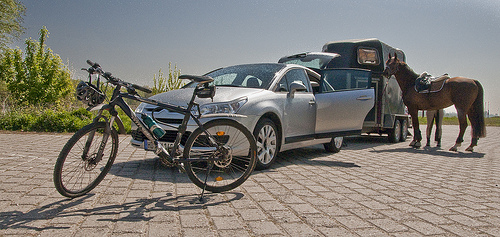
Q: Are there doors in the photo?
A: Yes, there is a door.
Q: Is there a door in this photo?
A: Yes, there is a door.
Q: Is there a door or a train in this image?
A: Yes, there is a door.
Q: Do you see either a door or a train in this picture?
A: Yes, there is a door.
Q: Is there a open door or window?
A: Yes, there is an open door.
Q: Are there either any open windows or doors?
A: Yes, there is an open door.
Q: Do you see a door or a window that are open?
A: Yes, the door is open.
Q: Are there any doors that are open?
A: Yes, there is an open door.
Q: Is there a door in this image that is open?
A: Yes, there is a door that is open.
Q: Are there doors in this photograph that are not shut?
A: Yes, there is a open door.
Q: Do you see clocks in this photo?
A: No, there are no clocks.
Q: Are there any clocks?
A: No, there are no clocks.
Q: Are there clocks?
A: No, there are no clocks.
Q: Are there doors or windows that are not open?
A: No, there is a door but it is open.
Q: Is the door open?
A: Yes, the door is open.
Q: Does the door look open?
A: Yes, the door is open.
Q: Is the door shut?
A: No, the door is open.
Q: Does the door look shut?
A: No, the door is open.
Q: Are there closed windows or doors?
A: No, there is a door but it is open.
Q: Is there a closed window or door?
A: No, there is a door but it is open.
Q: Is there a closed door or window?
A: No, there is a door but it is open.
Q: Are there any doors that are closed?
A: No, there is a door but it is open.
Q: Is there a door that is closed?
A: No, there is a door but it is open.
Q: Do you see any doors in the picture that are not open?
A: No, there is a door but it is open.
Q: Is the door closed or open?
A: The door is open.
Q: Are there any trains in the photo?
A: No, there are no trains.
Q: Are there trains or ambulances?
A: No, there are no trains or ambulances.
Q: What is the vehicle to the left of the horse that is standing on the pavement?
A: The vehicle is a trailer.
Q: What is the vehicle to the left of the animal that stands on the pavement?
A: The vehicle is a trailer.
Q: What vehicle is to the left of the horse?
A: The vehicle is a trailer.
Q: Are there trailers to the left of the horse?
A: Yes, there is a trailer to the left of the horse.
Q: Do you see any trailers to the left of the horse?
A: Yes, there is a trailer to the left of the horse.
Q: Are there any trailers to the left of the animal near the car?
A: Yes, there is a trailer to the left of the horse.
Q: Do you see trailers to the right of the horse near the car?
A: No, the trailer is to the left of the horse.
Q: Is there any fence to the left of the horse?
A: No, there is a trailer to the left of the horse.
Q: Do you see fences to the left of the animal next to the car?
A: No, there is a trailer to the left of the horse.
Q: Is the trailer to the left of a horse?
A: Yes, the trailer is to the left of a horse.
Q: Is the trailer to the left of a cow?
A: No, the trailer is to the left of a horse.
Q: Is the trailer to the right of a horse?
A: No, the trailer is to the left of a horse.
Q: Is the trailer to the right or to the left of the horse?
A: The trailer is to the left of the horse.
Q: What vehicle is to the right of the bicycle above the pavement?
A: The vehicle is a trailer.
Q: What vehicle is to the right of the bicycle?
A: The vehicle is a trailer.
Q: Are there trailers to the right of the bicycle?
A: Yes, there is a trailer to the right of the bicycle.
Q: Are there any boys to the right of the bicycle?
A: No, there is a trailer to the right of the bicycle.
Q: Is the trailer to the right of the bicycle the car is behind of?
A: Yes, the trailer is to the right of the bicycle.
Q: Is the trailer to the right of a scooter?
A: No, the trailer is to the right of the bicycle.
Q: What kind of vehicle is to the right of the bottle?
A: The vehicle is a trailer.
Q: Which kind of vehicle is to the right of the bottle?
A: The vehicle is a trailer.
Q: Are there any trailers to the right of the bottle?
A: Yes, there is a trailer to the right of the bottle.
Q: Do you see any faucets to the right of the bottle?
A: No, there is a trailer to the right of the bottle.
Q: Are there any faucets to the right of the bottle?
A: No, there is a trailer to the right of the bottle.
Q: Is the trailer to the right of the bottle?
A: Yes, the trailer is to the right of the bottle.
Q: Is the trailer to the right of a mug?
A: No, the trailer is to the right of the bottle.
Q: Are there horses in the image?
A: Yes, there is a horse.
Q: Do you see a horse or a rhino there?
A: Yes, there is a horse.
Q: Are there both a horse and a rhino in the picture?
A: No, there is a horse but no rhinos.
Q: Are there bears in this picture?
A: No, there are no bears.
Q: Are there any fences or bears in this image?
A: No, there are no bears or fences.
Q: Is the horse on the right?
A: Yes, the horse is on the right of the image.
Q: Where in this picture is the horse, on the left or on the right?
A: The horse is on the right of the image.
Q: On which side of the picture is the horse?
A: The horse is on the right of the image.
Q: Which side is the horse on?
A: The horse is on the right of the image.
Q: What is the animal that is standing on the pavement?
A: The animal is a horse.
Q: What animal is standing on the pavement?
A: The animal is a horse.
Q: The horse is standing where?
A: The horse is standing on the pavement.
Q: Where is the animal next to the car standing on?
A: The horse is standing on the pavement.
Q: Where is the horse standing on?
A: The horse is standing on the pavement.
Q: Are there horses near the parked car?
A: Yes, there is a horse near the car.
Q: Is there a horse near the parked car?
A: Yes, there is a horse near the car.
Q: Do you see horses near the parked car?
A: Yes, there is a horse near the car.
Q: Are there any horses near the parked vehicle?
A: Yes, there is a horse near the car.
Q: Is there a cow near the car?
A: No, there is a horse near the car.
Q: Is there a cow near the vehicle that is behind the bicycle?
A: No, there is a horse near the car.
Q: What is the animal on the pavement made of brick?
A: The animal is a horse.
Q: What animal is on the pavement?
A: The animal is a horse.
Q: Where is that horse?
A: The horse is on the pavement.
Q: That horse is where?
A: The horse is on the pavement.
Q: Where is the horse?
A: The horse is on the pavement.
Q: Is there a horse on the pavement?
A: Yes, there is a horse on the pavement.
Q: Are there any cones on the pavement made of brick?
A: No, there is a horse on the pavement.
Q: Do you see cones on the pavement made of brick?
A: No, there is a horse on the pavement.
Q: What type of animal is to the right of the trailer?
A: The animal is a horse.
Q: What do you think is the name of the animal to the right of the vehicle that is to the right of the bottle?
A: The animal is a horse.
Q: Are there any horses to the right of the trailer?
A: Yes, there is a horse to the right of the trailer.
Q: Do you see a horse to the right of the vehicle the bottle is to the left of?
A: Yes, there is a horse to the right of the trailer.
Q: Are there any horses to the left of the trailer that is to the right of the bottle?
A: No, the horse is to the right of the trailer.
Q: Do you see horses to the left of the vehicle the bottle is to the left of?
A: No, the horse is to the right of the trailer.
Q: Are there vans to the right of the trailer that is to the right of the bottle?
A: No, there is a horse to the right of the trailer.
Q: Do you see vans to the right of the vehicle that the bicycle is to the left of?
A: No, there is a horse to the right of the trailer.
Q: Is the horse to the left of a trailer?
A: No, the horse is to the right of a trailer.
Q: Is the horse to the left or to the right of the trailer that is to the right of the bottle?
A: The horse is to the right of the trailer.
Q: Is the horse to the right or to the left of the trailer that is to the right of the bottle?
A: The horse is to the right of the trailer.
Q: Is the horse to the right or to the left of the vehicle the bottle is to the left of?
A: The horse is to the right of the trailer.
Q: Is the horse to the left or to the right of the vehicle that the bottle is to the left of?
A: The horse is to the right of the trailer.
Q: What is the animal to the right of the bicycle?
A: The animal is a horse.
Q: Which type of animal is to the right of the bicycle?
A: The animal is a horse.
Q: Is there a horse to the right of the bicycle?
A: Yes, there is a horse to the right of the bicycle.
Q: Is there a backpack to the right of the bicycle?
A: No, there is a horse to the right of the bicycle.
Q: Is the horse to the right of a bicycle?
A: Yes, the horse is to the right of a bicycle.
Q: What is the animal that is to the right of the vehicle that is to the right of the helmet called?
A: The animal is a horse.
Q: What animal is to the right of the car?
A: The animal is a horse.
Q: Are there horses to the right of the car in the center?
A: Yes, there is a horse to the right of the car.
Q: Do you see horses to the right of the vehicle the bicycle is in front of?
A: Yes, there is a horse to the right of the car.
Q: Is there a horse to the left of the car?
A: No, the horse is to the right of the car.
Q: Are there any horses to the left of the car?
A: No, the horse is to the right of the car.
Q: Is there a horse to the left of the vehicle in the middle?
A: No, the horse is to the right of the car.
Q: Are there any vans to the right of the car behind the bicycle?
A: No, there is a horse to the right of the car.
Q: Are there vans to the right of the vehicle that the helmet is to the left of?
A: No, there is a horse to the right of the car.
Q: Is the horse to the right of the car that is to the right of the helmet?
A: Yes, the horse is to the right of the car.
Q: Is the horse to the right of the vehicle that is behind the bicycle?
A: Yes, the horse is to the right of the car.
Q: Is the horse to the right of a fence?
A: No, the horse is to the right of the car.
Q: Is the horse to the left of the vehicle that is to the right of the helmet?
A: No, the horse is to the right of the car.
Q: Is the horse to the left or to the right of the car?
A: The horse is to the right of the car.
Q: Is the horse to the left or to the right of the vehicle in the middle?
A: The horse is to the right of the car.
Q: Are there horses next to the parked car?
A: Yes, there is a horse next to the car.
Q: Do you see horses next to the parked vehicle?
A: Yes, there is a horse next to the car.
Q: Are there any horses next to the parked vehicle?
A: Yes, there is a horse next to the car.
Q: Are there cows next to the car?
A: No, there is a horse next to the car.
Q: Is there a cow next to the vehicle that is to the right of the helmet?
A: No, there is a horse next to the car.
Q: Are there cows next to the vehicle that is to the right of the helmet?
A: No, there is a horse next to the car.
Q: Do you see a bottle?
A: Yes, there is a bottle.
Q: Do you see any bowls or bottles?
A: Yes, there is a bottle.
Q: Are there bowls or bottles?
A: Yes, there is a bottle.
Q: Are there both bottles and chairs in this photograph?
A: No, there is a bottle but no chairs.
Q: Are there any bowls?
A: No, there are no bowls.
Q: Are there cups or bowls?
A: No, there are no bowls or cups.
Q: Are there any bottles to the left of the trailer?
A: Yes, there is a bottle to the left of the trailer.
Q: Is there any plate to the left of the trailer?
A: No, there is a bottle to the left of the trailer.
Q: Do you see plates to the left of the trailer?
A: No, there is a bottle to the left of the trailer.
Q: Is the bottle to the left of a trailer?
A: Yes, the bottle is to the left of a trailer.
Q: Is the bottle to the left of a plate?
A: No, the bottle is to the left of a trailer.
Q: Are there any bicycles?
A: Yes, there is a bicycle.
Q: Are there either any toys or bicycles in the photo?
A: Yes, there is a bicycle.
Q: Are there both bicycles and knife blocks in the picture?
A: No, there is a bicycle but no knife blocks.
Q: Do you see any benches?
A: No, there are no benches.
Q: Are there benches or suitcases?
A: No, there are no benches or suitcases.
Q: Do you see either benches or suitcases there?
A: No, there are no benches or suitcases.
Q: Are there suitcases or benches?
A: No, there are no benches or suitcases.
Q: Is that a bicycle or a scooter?
A: That is a bicycle.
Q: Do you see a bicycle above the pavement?
A: Yes, there is a bicycle above the pavement.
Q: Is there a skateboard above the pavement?
A: No, there is a bicycle above the pavement.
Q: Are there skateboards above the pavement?
A: No, there is a bicycle above the pavement.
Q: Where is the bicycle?
A: The bicycle is on the pavement.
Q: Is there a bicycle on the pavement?
A: Yes, there is a bicycle on the pavement.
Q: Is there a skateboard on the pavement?
A: No, there is a bicycle on the pavement.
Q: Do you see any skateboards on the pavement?
A: No, there is a bicycle on the pavement.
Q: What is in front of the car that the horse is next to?
A: The bicycle is in front of the car.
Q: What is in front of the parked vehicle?
A: The bicycle is in front of the car.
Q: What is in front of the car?
A: The bicycle is in front of the car.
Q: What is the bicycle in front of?
A: The bicycle is in front of the car.